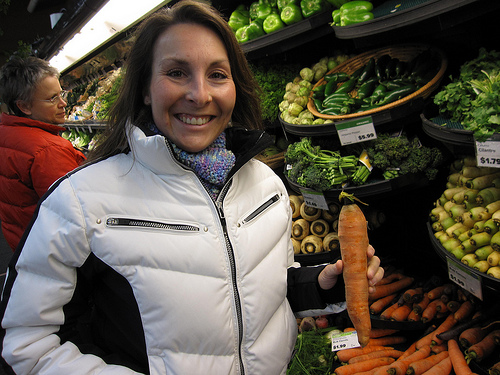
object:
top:
[335, 189, 361, 207]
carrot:
[336, 189, 371, 345]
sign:
[333, 114, 378, 144]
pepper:
[322, 95, 357, 107]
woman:
[0, 0, 380, 375]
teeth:
[178, 115, 214, 124]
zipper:
[240, 193, 282, 226]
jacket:
[0, 114, 350, 374]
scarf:
[166, 127, 238, 187]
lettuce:
[247, 68, 286, 123]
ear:
[141, 82, 153, 106]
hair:
[78, 0, 265, 161]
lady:
[0, 50, 92, 262]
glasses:
[34, 87, 72, 103]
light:
[45, 0, 166, 79]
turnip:
[301, 235, 323, 259]